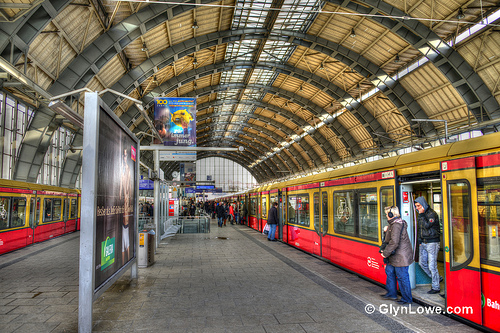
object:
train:
[205, 134, 498, 330]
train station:
[0, 0, 500, 332]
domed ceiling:
[0, 1, 497, 180]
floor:
[0, 213, 487, 333]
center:
[133, 115, 375, 258]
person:
[267, 202, 278, 241]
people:
[379, 205, 414, 304]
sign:
[155, 97, 196, 162]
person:
[379, 206, 414, 302]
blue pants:
[384, 264, 413, 304]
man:
[414, 196, 444, 293]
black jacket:
[417, 206, 440, 244]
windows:
[333, 187, 379, 242]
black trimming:
[353, 189, 359, 237]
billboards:
[153, 97, 197, 161]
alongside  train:
[75, 232, 253, 333]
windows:
[205, 0, 328, 157]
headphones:
[388, 206, 394, 218]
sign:
[92, 108, 136, 296]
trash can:
[138, 232, 155, 268]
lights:
[180, 10, 282, 147]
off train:
[395, 155, 483, 329]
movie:
[152, 98, 196, 150]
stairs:
[181, 218, 210, 234]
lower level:
[179, 214, 211, 233]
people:
[215, 201, 225, 228]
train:
[0, 177, 81, 256]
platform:
[76, 91, 140, 333]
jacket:
[378, 218, 413, 267]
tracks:
[4, 229, 80, 254]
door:
[396, 170, 447, 312]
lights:
[49, 87, 143, 110]